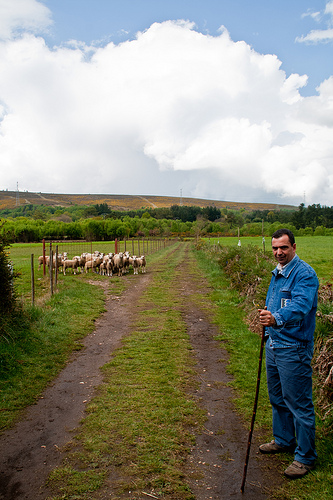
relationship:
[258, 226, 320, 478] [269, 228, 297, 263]
man has head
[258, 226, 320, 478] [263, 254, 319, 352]
man wearing clothing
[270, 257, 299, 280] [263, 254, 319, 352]
collar on clothing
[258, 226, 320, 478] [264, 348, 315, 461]
man wearing pants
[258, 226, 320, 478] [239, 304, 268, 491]
man holding stick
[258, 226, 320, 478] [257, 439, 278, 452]
man wearing shoe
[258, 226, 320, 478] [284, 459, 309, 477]
man wearing shoe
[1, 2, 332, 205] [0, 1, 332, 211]
clouds in clouds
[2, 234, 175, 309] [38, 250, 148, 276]
fence next to animals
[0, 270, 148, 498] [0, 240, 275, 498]
rut in path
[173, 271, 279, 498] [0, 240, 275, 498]
rut in path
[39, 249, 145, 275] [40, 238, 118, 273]
animals exiting through gate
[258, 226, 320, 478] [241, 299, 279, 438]
man holding stick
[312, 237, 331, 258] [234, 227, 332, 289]
grass in field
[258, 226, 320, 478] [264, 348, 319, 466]
man wearing pants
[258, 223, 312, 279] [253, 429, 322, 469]
man wearing shoes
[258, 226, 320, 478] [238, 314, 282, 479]
man holding stick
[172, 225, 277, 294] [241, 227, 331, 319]
field behind man